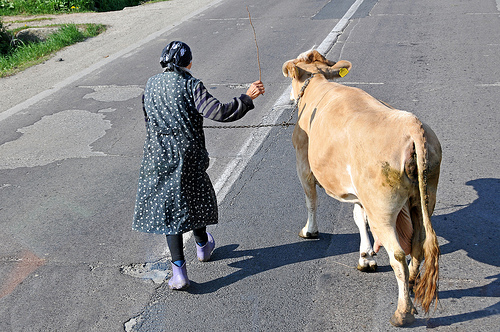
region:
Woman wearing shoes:
[160, 227, 225, 292]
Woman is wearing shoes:
[164, 227, 217, 291]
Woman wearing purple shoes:
[160, 235, 220, 295]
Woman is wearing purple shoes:
[165, 229, 217, 292]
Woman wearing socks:
[171, 237, 207, 266]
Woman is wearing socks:
[166, 238, 210, 263]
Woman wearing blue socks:
[165, 234, 210, 266]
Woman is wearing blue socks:
[166, 235, 208, 267]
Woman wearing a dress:
[130, 70, 224, 235]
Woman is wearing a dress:
[130, 61, 232, 234]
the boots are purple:
[134, 225, 230, 294]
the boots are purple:
[149, 223, 262, 313]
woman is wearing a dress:
[126, 60, 227, 251]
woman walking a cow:
[116, 28, 481, 308]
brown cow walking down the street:
[268, 40, 450, 297]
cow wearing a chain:
[224, 35, 459, 312]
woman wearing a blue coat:
[129, 29, 263, 279]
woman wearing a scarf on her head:
[127, 25, 254, 267]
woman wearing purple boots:
[113, 46, 234, 290]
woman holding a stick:
[122, 11, 280, 281]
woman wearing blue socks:
[124, 27, 251, 284]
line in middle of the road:
[188, 5, 360, 275]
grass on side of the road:
[4, 3, 83, 56]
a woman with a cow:
[126, 29, 468, 314]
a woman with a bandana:
[138, 30, 205, 86]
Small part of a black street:
[297, 258, 323, 293]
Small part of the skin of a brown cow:
[321, 121, 353, 149]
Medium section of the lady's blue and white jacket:
[153, 107, 186, 158]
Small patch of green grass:
[10, 48, 25, 62]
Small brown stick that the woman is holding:
[248, 8, 265, 80]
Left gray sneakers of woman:
[170, 268, 192, 292]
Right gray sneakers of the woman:
[191, 243, 218, 262]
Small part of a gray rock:
[20, 30, 35, 39]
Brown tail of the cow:
[416, 222, 449, 315]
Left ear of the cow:
[281, 60, 297, 74]